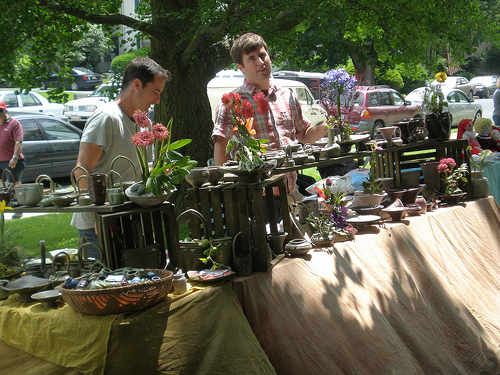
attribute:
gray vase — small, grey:
[14, 182, 46, 206]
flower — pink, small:
[153, 123, 167, 139]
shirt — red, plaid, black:
[223, 31, 319, 149]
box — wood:
[96, 202, 183, 273]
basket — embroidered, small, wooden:
[57, 261, 174, 318]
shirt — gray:
[68, 102, 153, 225]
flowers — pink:
[201, 88, 398, 168]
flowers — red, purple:
[221, 66, 361, 170]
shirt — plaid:
[206, 82, 306, 183]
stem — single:
[335, 114, 351, 151]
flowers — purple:
[310, 60, 365, 142]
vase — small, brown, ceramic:
[283, 237, 313, 256]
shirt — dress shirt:
[256, 96, 291, 144]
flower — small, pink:
[136, 128, 151, 142]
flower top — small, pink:
[130, 107, 157, 129]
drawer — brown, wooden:
[93, 209, 186, 256]